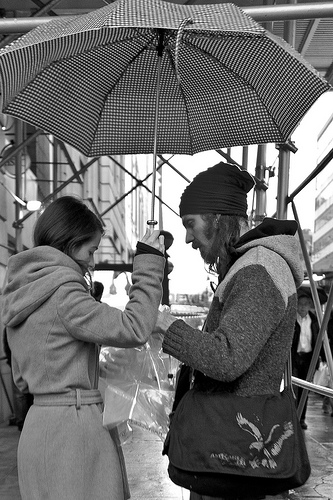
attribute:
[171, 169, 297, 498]
man — shaggy, in rain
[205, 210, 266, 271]
hair — shaggy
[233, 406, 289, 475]
eagle — image, screen printed, american, graphic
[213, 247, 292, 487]
jacket — long, fleece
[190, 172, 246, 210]
hat — sock, beanie, saggy, wrinkled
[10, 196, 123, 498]
woman — nicely groomed, in rain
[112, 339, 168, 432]
bag — plastic, center, focus, shiny, transparent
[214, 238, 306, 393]
hoodie — three toned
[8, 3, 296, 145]
umbrella — open, hounds tooth, black, white, plaid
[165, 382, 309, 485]
shoulder bag — black, cloth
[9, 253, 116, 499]
coat — large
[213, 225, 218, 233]
earring — metal, silver, shiny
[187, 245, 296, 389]
sweater — hooded, heavy knit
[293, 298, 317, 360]
man — older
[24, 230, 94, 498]
jacket — soft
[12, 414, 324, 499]
tarmac — black, wet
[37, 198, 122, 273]
head — looking downward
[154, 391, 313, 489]
satchel — bird pattern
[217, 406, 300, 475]
insignia — bird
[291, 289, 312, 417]
pedestrian — distant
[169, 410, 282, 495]
bag — dark, messenger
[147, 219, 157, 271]
handle — silver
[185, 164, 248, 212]
beanie — black, striped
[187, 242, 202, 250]
mustache — thick